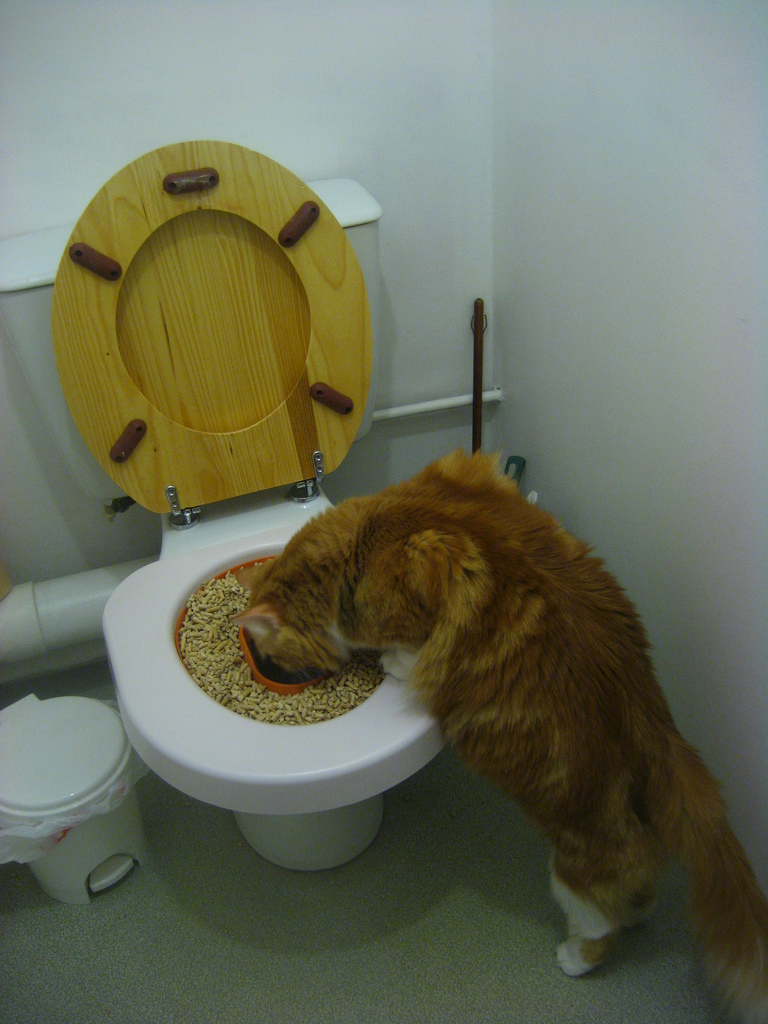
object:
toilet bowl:
[100, 496, 449, 816]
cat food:
[249, 636, 306, 683]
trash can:
[0, 693, 152, 907]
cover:
[0, 692, 128, 812]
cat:
[233, 444, 768, 1024]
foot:
[557, 937, 613, 976]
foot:
[625, 887, 658, 930]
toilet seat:
[50, 135, 373, 515]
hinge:
[165, 484, 200, 531]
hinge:
[289, 451, 324, 505]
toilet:
[56, 142, 440, 875]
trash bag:
[0, 756, 147, 868]